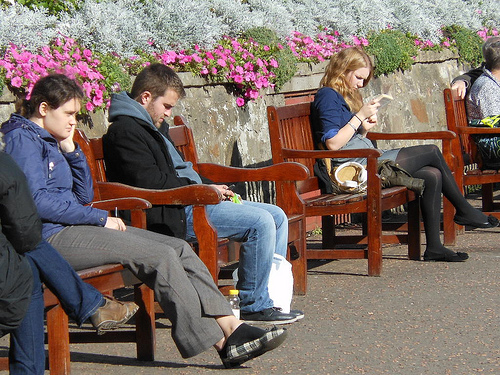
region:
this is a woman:
[11, 53, 308, 373]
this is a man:
[105, 31, 320, 331]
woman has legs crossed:
[302, 29, 490, 282]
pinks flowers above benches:
[20, 9, 498, 128]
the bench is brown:
[240, 63, 468, 271]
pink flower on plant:
[9, 46, 23, 59]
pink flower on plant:
[7, 74, 22, 90]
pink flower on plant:
[83, 99, 94, 111]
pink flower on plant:
[91, 94, 103, 106]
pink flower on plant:
[70, 51, 82, 63]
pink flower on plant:
[235, 95, 244, 107]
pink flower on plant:
[191, 53, 204, 64]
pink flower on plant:
[255, 56, 266, 66]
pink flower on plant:
[268, 57, 279, 69]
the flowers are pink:
[162, 25, 287, 100]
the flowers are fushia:
[291, 15, 343, 62]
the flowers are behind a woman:
[283, 10, 495, 282]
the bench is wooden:
[252, 83, 471, 275]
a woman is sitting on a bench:
[238, 30, 485, 274]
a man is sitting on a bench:
[103, 57, 310, 322]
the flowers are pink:
[12, 30, 114, 107]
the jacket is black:
[96, 95, 191, 240]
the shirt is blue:
[319, 79, 367, 136]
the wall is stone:
[380, 48, 452, 140]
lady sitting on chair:
[307, 32, 499, 284]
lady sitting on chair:
[106, 59, 318, 343]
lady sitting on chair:
[0, 51, 275, 373]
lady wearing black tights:
[388, 136, 498, 262]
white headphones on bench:
[332, 149, 397, 203]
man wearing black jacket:
[88, 91, 244, 254]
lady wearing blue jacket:
[0, 94, 131, 244]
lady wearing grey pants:
[43, 211, 264, 368]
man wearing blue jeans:
[179, 184, 301, 303]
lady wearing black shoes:
[451, 200, 498, 240]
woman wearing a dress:
[301, 31, 497, 249]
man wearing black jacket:
[125, 73, 240, 215]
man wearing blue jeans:
[111, 55, 243, 205]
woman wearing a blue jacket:
[30, 67, 137, 244]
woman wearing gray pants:
[43, 77, 133, 262]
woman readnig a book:
[325, 42, 426, 158]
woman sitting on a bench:
[326, 35, 496, 265]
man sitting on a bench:
[131, 57, 241, 208]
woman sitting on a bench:
[45, 75, 123, 255]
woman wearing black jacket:
[5, 154, 32, 369]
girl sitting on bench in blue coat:
[6, 77, 293, 367]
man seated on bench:
[108, 64, 305, 322]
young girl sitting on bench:
[308, 47, 498, 277]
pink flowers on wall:
[1, 44, 418, 107]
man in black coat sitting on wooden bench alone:
[70, 58, 314, 327]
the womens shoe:
[234, 327, 286, 352]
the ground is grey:
[341, 300, 393, 338]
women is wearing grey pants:
[67, 223, 142, 258]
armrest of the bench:
[173, 184, 213, 201]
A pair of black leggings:
[390, 135, 497, 260]